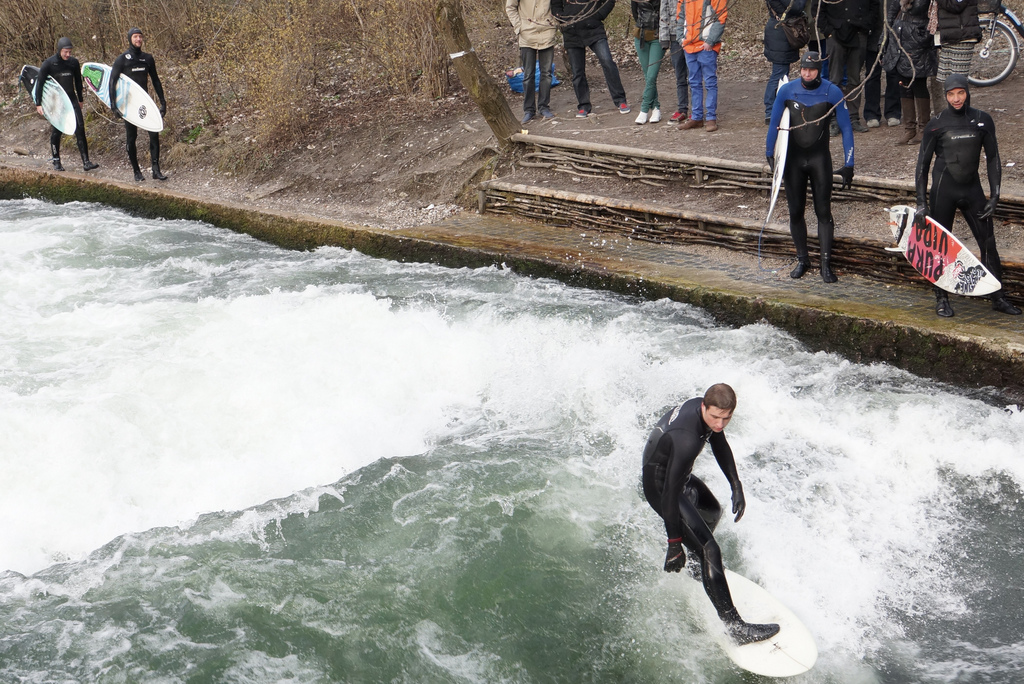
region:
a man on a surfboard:
[626, 354, 819, 681]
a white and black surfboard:
[21, 62, 88, 138]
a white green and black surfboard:
[79, 59, 181, 143]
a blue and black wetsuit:
[757, 57, 872, 293]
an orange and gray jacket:
[660, 2, 725, 60]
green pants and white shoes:
[626, 32, 677, 128]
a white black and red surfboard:
[875, 199, 1012, 321]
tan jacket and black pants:
[508, 4, 573, 140]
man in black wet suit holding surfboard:
[874, 68, 1018, 321]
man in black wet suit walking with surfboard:
[83, 23, 167, 182]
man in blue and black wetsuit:
[760, 46, 858, 281]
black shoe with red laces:
[612, 96, 628, 113]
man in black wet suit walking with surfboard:
[15, 31, 102, 172]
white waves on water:
[89, 289, 577, 561]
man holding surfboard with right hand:
[880, 78, 1017, 326]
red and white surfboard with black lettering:
[882, 202, 1001, 302]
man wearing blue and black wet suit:
[759, 46, 861, 281]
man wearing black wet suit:
[913, 75, 1013, 319]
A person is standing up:
[758, 40, 870, 297]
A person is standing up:
[898, 68, 1017, 325]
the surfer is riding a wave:
[644, 376, 822, 677]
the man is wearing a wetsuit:
[632, 395, 782, 640]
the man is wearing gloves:
[663, 537, 687, 573]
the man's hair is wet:
[702, 382, 735, 417]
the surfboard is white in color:
[670, 549, 816, 682]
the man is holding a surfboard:
[764, 67, 796, 220]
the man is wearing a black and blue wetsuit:
[765, 75, 857, 279]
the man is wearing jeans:
[686, 47, 719, 125]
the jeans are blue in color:
[678, 50, 720, 115]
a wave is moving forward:
[2, 288, 603, 576]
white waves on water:
[78, 309, 411, 595]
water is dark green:
[111, 317, 731, 597]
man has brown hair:
[672, 370, 774, 413]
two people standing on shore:
[0, 34, 184, 203]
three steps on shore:
[476, 89, 868, 276]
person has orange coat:
[675, 1, 733, 50]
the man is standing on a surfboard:
[637, 382, 818, 677]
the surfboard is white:
[680, 553, 818, 675]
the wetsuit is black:
[643, 395, 746, 631]